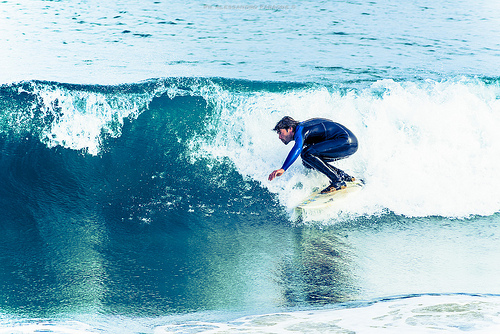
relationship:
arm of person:
[285, 136, 310, 168] [267, 114, 359, 195]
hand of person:
[267, 164, 290, 182] [256, 104, 378, 202]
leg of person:
[301, 139, 343, 182] [267, 114, 359, 195]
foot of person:
[320, 181, 345, 193] [267, 114, 359, 195]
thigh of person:
[301, 138, 343, 160] [267, 114, 359, 195]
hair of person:
[275, 114, 300, 137] [239, 68, 394, 213]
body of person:
[312, 117, 357, 164] [262, 110, 364, 195]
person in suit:
[267, 114, 359, 195] [278, 116, 357, 186]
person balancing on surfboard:
[227, 92, 407, 223] [304, 190, 386, 220]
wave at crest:
[0, 76, 500, 225] [24, 82, 497, 227]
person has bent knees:
[267, 114, 359, 195] [290, 145, 326, 170]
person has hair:
[267, 114, 359, 195] [273, 114, 301, 130]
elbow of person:
[288, 144, 303, 156] [267, 114, 359, 195]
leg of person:
[301, 139, 343, 182] [268, 114, 368, 210]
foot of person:
[335, 173, 355, 183] [267, 114, 359, 195]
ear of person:
[288, 122, 295, 137] [267, 114, 359, 195]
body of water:
[93, 15, 314, 86] [99, 49, 462, 332]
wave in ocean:
[44, 67, 195, 216] [3, 23, 116, 230]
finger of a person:
[257, 162, 292, 184] [249, 89, 385, 226]